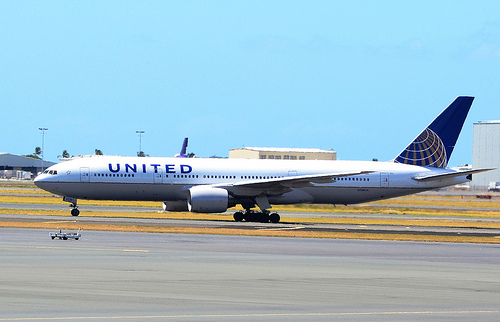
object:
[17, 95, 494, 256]
airplane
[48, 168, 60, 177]
window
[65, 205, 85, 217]
wheel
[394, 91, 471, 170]
tail